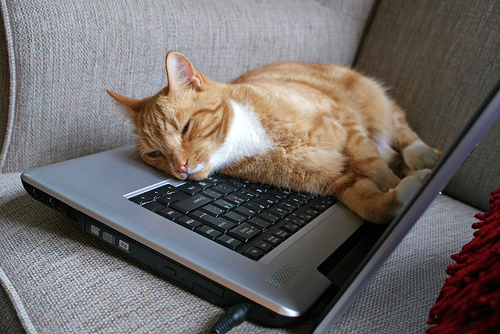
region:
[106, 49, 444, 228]
orange and white cat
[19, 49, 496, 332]
cat laying on a laptop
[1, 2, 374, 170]
arm of gray and white chair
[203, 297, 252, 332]
charger for the laptop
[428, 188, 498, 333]
ref fringe used as trim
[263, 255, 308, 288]
speaker for the laptop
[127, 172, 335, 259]
keys for the laptop keyboard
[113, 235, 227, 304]
door that opens for cd'd and dvd's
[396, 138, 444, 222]
two white paws from the cat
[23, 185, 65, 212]
two usb ports on the side of laptop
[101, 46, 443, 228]
this cat looks sleepy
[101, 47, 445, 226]
this cat looks very comfortable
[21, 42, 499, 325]
cat laying on a laptop computer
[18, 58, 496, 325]
this computer probably needs vacuuming for cat hair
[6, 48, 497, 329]
a cat on a laptop on a chair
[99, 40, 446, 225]
this cat has tabby stripes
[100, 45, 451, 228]
this cat is different shades of brown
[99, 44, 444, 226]
this cat has a white ruff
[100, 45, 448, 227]
this cat has white paws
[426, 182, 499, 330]
a red throw pillow on a chair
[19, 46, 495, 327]
Cat lying on a bicycle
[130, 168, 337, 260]
Black keys on a keyboard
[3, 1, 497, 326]
Cat is on a couch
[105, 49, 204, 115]
Two ears on a cat's head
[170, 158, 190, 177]
Pink nose on a cat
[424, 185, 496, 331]
Red fringe pillow on the couch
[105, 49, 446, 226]
A brown and white cat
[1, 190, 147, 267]
A shadow on the couch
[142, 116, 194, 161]
Two eyes on the cat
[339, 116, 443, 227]
The legs of the cat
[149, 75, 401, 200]
A cat sleeping on a laptop.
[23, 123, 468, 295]
Laptop sitting in the chair.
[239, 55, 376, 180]
The cat is brown and white.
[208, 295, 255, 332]
Cord plug into laptop.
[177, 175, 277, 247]
The keys on the laptop.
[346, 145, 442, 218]
The cat feet is on the screen.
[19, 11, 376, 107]
The chair is gray.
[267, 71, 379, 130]
The cat has brown fur.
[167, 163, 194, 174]
The cat has a pinknose.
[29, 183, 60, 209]
Three holes on side of laptop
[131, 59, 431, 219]
cat lying on a laptop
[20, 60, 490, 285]
laptop on a couch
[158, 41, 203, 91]
ear on the cat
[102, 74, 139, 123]
ear on the cat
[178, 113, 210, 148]
eye on the cat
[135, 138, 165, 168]
eye on the cat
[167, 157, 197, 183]
nose on the cat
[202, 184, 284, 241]
keys on a keyboard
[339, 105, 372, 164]
stripes on a cat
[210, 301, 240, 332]
plug in the laptop